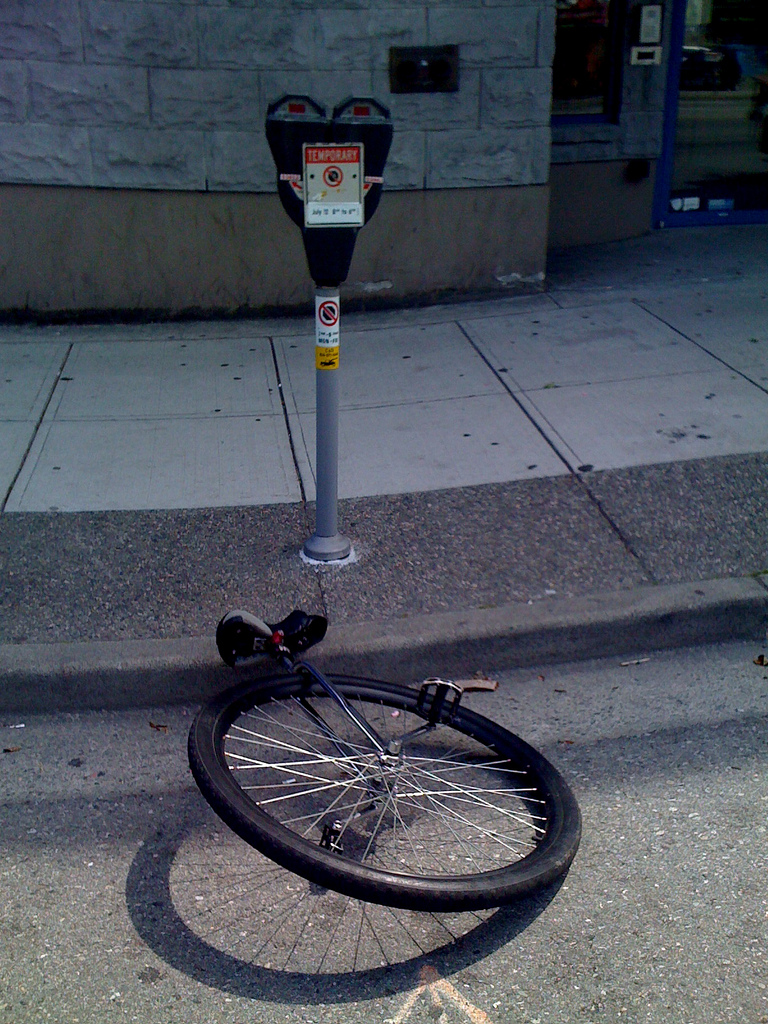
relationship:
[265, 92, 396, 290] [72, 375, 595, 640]
meter on sidewalk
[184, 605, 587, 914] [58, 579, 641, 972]
bike on street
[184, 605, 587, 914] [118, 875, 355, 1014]
bike has shadow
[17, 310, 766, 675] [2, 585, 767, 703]
sidewalk has curb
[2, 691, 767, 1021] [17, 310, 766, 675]
street by sidewalk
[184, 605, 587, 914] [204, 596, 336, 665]
bike has seat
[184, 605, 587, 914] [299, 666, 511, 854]
bike has pedals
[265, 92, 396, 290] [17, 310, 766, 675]
meter on sidewalk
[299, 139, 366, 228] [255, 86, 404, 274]
sign on parking meter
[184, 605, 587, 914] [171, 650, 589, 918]
bike has tire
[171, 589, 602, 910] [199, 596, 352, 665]
bike has seat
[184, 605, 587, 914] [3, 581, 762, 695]
bike side curb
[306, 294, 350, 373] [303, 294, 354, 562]
sticker on pole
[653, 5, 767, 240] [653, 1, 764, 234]
door has frame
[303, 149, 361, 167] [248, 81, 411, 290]
wording on parking meter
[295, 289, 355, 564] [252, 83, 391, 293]
pole connected meter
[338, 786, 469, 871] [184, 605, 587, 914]
spokes of bike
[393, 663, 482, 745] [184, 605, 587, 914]
pedal of bike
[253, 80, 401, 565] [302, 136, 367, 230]
meter with sign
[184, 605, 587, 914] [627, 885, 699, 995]
bike lying top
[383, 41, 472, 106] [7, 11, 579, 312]
plate on building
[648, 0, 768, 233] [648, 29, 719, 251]
door on building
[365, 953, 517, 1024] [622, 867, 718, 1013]
arrow on top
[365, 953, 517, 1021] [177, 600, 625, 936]
arrow pointing unicycle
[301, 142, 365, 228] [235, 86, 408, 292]
sign on meter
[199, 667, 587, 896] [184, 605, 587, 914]
tire of bike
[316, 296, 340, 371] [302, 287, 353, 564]
sticker on pole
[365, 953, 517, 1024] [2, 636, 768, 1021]
arrow painted street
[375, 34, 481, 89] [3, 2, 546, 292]
box on wall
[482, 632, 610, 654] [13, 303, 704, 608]
edge of sidewalk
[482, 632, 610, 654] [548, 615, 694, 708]
edge of curb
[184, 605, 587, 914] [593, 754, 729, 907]
bike on ground